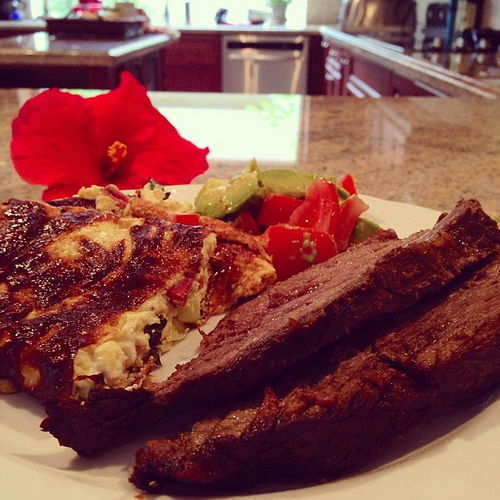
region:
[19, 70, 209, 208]
a flower is by the meal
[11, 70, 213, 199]
the flower is red in color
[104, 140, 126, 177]
the stem is on the flower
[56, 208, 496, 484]
meat is on the dish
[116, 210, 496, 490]
the meat is red brown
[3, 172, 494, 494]
the meal is served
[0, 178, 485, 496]
the food is on the dish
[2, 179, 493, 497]
the dish is white in color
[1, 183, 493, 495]
the dish is made of ceramic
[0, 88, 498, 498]
the table top is made of granite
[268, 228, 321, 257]
tomato on the plate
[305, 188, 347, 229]
tomato on the plate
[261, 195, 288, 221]
tomato on the plate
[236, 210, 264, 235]
tomato on the plate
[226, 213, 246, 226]
tomato on the plate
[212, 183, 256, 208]
avocado on the plate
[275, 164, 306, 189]
avocado on the plate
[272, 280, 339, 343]
steak on the plate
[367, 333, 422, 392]
steak on the plate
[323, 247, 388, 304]
steak on the plate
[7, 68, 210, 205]
Red flower by the plate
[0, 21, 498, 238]
Gray granite countertop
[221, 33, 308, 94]
Stainless steel dishwasher below the window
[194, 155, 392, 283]
Tomato and avocado mix on the white plate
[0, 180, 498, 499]
White dinner plate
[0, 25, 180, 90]
Kitchen island with granite counter top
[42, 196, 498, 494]
Sliced steak on the white plate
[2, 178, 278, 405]
Potato casserole with red and green peppers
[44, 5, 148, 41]
Brown basket on the kitchen island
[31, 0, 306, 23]
A window letting light into the kitchen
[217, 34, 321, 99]
a silver dish washer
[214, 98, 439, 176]
a counter top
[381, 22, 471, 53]
the stove in the kitchen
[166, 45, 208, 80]
a cabinet in the kitchen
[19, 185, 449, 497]
a plate of food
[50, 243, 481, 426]
meat on a plate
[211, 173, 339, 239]
salad on a plate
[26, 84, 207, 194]
a red flower on the counter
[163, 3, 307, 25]
a window in the kitchen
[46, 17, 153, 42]
a basket on the counter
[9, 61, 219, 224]
The flower is red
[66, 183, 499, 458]
The steak is well done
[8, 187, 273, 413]
The frittata is well done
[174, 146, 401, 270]
There are vegetables on the side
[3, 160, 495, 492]
The plate is white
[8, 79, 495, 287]
The counter is marble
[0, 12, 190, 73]
The island is near the counter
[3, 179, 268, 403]
The frittata is yellow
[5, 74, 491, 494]
The flower is next to the plate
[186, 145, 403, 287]
The vegetables are red and green